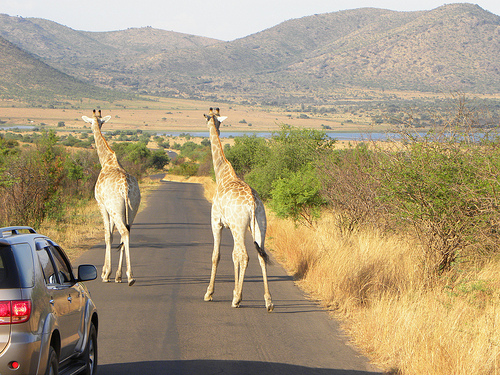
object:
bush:
[265, 169, 327, 233]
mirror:
[74, 263, 99, 281]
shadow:
[110, 259, 309, 286]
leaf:
[280, 160, 291, 176]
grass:
[158, 119, 499, 375]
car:
[0, 225, 99, 374]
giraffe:
[201, 106, 277, 313]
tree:
[166, 139, 182, 153]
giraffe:
[80, 106, 144, 285]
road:
[67, 177, 380, 374]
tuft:
[254, 241, 277, 269]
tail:
[248, 204, 276, 267]